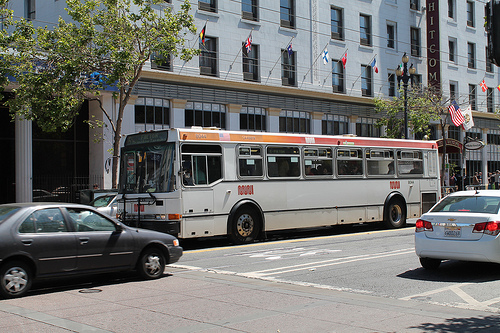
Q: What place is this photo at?
A: It is at the road.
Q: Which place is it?
A: It is a road.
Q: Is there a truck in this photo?
A: No, there are no trucks.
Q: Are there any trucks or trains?
A: No, there are no trucks or trains.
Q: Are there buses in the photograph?
A: Yes, there is a bus.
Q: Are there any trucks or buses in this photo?
A: Yes, there is a bus.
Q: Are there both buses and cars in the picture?
A: Yes, there are both a bus and a car.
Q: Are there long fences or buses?
A: Yes, there is a long bus.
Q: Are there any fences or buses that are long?
A: Yes, the bus is long.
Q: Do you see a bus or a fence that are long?
A: Yes, the bus is long.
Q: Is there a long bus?
A: Yes, there is a long bus.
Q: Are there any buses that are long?
A: Yes, there is a bus that is long.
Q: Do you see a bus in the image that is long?
A: Yes, there is a bus that is long.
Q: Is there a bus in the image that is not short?
A: Yes, there is a long bus.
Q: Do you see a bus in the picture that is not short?
A: Yes, there is a long bus.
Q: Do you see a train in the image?
A: No, there are no trains.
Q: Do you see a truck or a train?
A: No, there are no trains or trucks.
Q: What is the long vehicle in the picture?
A: The vehicle is a bus.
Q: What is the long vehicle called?
A: The vehicle is a bus.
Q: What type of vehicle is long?
A: The vehicle is a bus.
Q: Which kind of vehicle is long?
A: The vehicle is a bus.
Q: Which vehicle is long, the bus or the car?
A: The bus is long.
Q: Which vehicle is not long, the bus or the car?
A: The car is not long.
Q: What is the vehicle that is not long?
A: The vehicle is a car.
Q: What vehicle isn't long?
A: The vehicle is a car.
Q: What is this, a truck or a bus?
A: This is a bus.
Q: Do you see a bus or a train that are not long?
A: No, there is a bus but it is long.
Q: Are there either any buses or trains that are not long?
A: No, there is a bus but it is long.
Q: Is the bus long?
A: Yes, the bus is long.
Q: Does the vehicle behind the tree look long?
A: Yes, the bus is long.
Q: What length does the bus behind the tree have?
A: The bus has long length.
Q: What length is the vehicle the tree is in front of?
A: The bus is long.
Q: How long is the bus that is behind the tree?
A: The bus is long.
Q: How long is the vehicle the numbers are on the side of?
A: The bus is long.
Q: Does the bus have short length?
A: No, the bus is long.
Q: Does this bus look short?
A: No, the bus is long.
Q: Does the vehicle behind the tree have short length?
A: No, the bus is long.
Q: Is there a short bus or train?
A: No, there is a bus but it is long.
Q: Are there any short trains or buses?
A: No, there is a bus but it is long.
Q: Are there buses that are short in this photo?
A: No, there is a bus but it is long.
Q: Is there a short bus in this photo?
A: No, there is a bus but it is long.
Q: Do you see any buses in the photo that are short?
A: No, there is a bus but it is long.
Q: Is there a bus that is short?
A: No, there is a bus but it is long.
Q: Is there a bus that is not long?
A: No, there is a bus but it is long.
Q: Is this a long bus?
A: Yes, this is a long bus.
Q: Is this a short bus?
A: No, this is a long bus.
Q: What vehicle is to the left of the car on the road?
A: The vehicle is a bus.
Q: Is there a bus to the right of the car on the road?
A: No, the bus is to the left of the car.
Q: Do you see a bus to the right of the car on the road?
A: No, the bus is to the left of the car.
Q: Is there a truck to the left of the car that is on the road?
A: No, there is a bus to the left of the car.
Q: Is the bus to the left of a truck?
A: No, the bus is to the left of the car.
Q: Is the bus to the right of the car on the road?
A: No, the bus is to the left of the car.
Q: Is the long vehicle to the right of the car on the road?
A: No, the bus is to the left of the car.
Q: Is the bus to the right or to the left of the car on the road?
A: The bus is to the left of the car.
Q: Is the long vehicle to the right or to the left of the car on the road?
A: The bus is to the left of the car.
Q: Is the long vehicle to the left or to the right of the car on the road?
A: The bus is to the left of the car.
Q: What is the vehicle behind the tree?
A: The vehicle is a bus.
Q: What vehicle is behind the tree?
A: The vehicle is a bus.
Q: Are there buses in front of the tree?
A: No, the bus is behind the tree.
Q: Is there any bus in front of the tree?
A: No, the bus is behind the tree.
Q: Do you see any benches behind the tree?
A: No, there is a bus behind the tree.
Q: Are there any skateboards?
A: No, there are no skateboards.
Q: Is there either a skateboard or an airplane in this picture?
A: No, there are no skateboards or airplanes.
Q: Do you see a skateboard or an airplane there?
A: No, there are no skateboards or airplanes.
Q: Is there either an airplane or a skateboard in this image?
A: No, there are no skateboards or airplanes.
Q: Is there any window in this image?
A: Yes, there is a window.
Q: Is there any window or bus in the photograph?
A: Yes, there is a window.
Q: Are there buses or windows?
A: Yes, there is a window.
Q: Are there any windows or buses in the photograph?
A: Yes, there is a window.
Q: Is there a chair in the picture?
A: No, there are no chairs.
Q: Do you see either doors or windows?
A: Yes, there is a window.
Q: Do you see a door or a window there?
A: Yes, there is a window.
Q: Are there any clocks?
A: No, there are no clocks.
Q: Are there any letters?
A: Yes, there are letters.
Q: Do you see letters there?
A: Yes, there are letters.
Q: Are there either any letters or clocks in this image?
A: Yes, there are letters.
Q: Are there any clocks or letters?
A: Yes, there are letters.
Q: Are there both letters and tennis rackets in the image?
A: No, there are letters but no rackets.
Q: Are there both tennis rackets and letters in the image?
A: No, there are letters but no rackets.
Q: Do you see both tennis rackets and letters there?
A: No, there are letters but no rackets.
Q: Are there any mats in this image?
A: No, there are no mats.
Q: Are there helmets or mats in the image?
A: No, there are no mats or helmets.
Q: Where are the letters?
A: The letters are on the road.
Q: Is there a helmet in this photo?
A: No, there are no helmets.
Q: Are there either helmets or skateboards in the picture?
A: No, there are no helmets or skateboards.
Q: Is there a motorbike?
A: No, there are no motorcycles.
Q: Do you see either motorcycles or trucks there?
A: No, there are no motorcycles or trucks.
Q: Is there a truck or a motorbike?
A: No, there are no motorcycles or trucks.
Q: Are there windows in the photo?
A: Yes, there is a window.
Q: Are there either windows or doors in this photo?
A: Yes, there is a window.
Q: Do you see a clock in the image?
A: No, there are no clocks.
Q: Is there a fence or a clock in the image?
A: No, there are no clocks or fences.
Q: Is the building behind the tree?
A: Yes, the building is behind the tree.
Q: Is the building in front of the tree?
A: No, the building is behind the tree.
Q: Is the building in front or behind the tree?
A: The building is behind the tree.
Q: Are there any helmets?
A: No, there are no helmets.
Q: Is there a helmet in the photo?
A: No, there are no helmets.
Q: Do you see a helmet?
A: No, there are no helmets.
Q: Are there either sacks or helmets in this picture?
A: No, there are no helmets or sacks.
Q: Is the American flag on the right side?
A: Yes, the American flag is on the right of the image.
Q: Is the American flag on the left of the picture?
A: No, the American flag is on the right of the image.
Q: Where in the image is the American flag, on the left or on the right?
A: The American flag is on the right of the image.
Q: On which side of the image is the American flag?
A: The American flag is on the right of the image.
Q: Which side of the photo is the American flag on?
A: The American flag is on the right of the image.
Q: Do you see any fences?
A: No, there are no fences.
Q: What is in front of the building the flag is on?
A: The tree is in front of the building.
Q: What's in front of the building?
A: The tree is in front of the building.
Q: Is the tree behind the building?
A: No, the tree is in front of the building.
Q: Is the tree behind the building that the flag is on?
A: No, the tree is in front of the building.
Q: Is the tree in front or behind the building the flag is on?
A: The tree is in front of the building.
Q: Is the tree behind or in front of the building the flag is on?
A: The tree is in front of the building.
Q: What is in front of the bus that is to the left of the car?
A: The tree is in front of the bus.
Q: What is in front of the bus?
A: The tree is in front of the bus.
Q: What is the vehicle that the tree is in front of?
A: The vehicle is a bus.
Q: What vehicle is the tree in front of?
A: The tree is in front of the bus.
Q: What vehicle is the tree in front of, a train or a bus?
A: The tree is in front of a bus.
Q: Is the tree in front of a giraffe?
A: No, the tree is in front of a bus.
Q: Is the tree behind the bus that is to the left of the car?
A: No, the tree is in front of the bus.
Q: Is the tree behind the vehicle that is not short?
A: No, the tree is in front of the bus.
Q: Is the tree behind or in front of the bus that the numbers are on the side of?
A: The tree is in front of the bus.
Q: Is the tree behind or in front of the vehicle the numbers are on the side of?
A: The tree is in front of the bus.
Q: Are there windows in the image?
A: Yes, there is a window.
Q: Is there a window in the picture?
A: Yes, there is a window.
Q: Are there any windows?
A: Yes, there is a window.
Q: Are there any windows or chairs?
A: Yes, there is a window.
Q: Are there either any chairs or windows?
A: Yes, there is a window.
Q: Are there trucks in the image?
A: No, there are no trucks.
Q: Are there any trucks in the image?
A: No, there are no trucks.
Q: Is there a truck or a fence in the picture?
A: No, there are no trucks or fences.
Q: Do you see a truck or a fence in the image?
A: No, there are no trucks or fences.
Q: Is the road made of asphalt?
A: Yes, the road is made of asphalt.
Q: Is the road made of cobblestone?
A: No, the road is made of asphalt.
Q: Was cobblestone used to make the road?
A: No, the road is made of asphalt.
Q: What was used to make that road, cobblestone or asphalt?
A: The road is made of asphalt.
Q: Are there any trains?
A: No, there are no trains.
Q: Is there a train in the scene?
A: No, there are no trains.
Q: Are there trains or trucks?
A: No, there are no trains or trucks.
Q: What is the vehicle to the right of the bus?
A: The vehicle is a car.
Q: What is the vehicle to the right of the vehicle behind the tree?
A: The vehicle is a car.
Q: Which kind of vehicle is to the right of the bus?
A: The vehicle is a car.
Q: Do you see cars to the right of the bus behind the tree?
A: Yes, there is a car to the right of the bus.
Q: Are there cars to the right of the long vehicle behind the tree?
A: Yes, there is a car to the right of the bus.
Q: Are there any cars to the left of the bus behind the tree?
A: No, the car is to the right of the bus.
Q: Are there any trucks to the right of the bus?
A: No, there is a car to the right of the bus.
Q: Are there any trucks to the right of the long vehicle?
A: No, there is a car to the right of the bus.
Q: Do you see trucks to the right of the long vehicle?
A: No, there is a car to the right of the bus.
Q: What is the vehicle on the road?
A: The vehicle is a car.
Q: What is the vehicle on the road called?
A: The vehicle is a car.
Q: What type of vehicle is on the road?
A: The vehicle is a car.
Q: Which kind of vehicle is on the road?
A: The vehicle is a car.